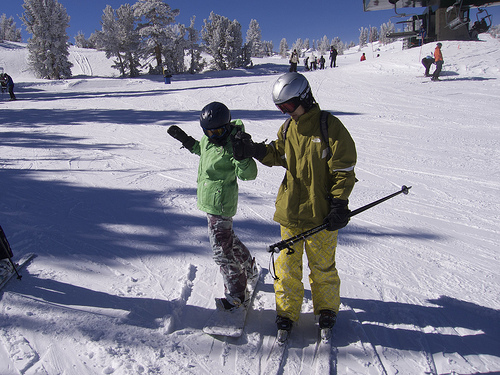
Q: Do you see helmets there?
A: Yes, there is a helmet.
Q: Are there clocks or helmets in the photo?
A: Yes, there is a helmet.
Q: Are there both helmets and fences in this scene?
A: No, there is a helmet but no fences.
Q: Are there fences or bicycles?
A: No, there are no fences or bicycles.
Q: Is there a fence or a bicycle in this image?
A: No, there are no fences or bicycles.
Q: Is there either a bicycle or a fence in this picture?
A: No, there are no fences or bicycles.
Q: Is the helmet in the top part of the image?
A: Yes, the helmet is in the top of the image.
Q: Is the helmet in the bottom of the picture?
A: No, the helmet is in the top of the image.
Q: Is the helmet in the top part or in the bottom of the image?
A: The helmet is in the top of the image.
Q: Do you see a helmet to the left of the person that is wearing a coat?
A: Yes, there is a helmet to the left of the person.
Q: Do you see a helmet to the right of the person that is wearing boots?
A: No, the helmet is to the left of the person.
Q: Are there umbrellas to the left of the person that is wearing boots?
A: No, there is a helmet to the left of the person.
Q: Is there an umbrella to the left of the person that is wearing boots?
A: No, there is a helmet to the left of the person.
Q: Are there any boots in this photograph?
A: Yes, there are boots.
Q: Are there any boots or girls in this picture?
A: Yes, there are boots.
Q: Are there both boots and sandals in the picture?
A: No, there are boots but no sandals.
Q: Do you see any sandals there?
A: No, there are no sandals.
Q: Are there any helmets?
A: Yes, there is a helmet.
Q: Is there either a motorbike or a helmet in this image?
A: Yes, there is a helmet.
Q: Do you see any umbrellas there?
A: No, there are no umbrellas.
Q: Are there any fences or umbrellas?
A: No, there are no umbrellas or fences.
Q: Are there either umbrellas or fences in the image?
A: No, there are no umbrellas or fences.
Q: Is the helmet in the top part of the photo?
A: Yes, the helmet is in the top of the image.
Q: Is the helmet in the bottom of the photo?
A: No, the helmet is in the top of the image.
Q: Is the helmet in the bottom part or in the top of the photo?
A: The helmet is in the top of the image.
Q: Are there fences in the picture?
A: No, there are no fences.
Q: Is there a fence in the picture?
A: No, there are no fences.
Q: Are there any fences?
A: No, there are no fences.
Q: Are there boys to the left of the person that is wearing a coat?
A: Yes, there is a boy to the left of the person.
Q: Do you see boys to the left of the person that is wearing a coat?
A: Yes, there is a boy to the left of the person.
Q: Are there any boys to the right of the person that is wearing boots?
A: No, the boy is to the left of the person.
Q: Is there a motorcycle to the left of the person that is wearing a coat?
A: No, there is a boy to the left of the person.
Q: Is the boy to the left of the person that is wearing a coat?
A: Yes, the boy is to the left of the person.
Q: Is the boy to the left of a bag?
A: No, the boy is to the left of the person.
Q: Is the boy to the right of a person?
A: No, the boy is to the left of a person.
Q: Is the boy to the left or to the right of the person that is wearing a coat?
A: The boy is to the left of the person.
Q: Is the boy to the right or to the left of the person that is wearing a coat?
A: The boy is to the left of the person.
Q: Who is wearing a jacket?
A: The boy is wearing a jacket.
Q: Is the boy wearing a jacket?
A: Yes, the boy is wearing a jacket.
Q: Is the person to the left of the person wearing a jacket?
A: Yes, the boy is wearing a jacket.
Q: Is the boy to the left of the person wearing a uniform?
A: No, the boy is wearing a jacket.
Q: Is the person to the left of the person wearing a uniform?
A: No, the boy is wearing a jacket.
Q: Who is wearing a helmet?
A: The boy is wearing a helmet.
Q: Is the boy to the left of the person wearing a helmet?
A: Yes, the boy is wearing a helmet.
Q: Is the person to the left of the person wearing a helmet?
A: Yes, the boy is wearing a helmet.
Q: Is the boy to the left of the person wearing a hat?
A: No, the boy is wearing a helmet.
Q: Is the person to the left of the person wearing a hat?
A: No, the boy is wearing a helmet.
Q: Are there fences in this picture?
A: No, there are no fences.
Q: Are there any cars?
A: No, there are no cars.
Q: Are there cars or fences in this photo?
A: No, there are no cars or fences.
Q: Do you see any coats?
A: Yes, there is a coat.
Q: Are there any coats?
A: Yes, there is a coat.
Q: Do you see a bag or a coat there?
A: Yes, there is a coat.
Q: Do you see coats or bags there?
A: Yes, there is a coat.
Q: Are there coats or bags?
A: Yes, there is a coat.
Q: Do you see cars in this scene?
A: No, there are no cars.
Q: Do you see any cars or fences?
A: No, there are no cars or fences.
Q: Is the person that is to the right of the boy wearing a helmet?
A: Yes, the person is wearing a helmet.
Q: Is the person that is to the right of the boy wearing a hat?
A: No, the person is wearing a helmet.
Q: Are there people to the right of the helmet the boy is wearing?
A: Yes, there is a person to the right of the helmet.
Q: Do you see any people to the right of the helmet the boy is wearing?
A: Yes, there is a person to the right of the helmet.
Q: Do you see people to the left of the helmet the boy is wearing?
A: No, the person is to the right of the helmet.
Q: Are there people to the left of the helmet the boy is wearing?
A: No, the person is to the right of the helmet.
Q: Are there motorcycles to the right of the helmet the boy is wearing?
A: No, there is a person to the right of the helmet.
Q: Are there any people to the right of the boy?
A: Yes, there is a person to the right of the boy.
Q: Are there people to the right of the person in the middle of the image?
A: Yes, there is a person to the right of the boy.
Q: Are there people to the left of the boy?
A: No, the person is to the right of the boy.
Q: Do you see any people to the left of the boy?
A: No, the person is to the right of the boy.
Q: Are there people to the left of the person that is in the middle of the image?
A: No, the person is to the right of the boy.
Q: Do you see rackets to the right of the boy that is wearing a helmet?
A: No, there is a person to the right of the boy.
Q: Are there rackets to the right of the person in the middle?
A: No, there is a person to the right of the boy.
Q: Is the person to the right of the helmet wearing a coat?
A: Yes, the person is wearing a coat.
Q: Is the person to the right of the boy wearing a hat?
A: No, the person is wearing a coat.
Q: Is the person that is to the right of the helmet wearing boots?
A: Yes, the person is wearing boots.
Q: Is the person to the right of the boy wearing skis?
A: No, the person is wearing boots.